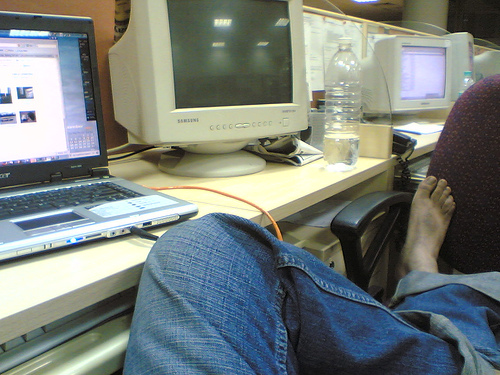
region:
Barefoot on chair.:
[397, 169, 459, 283]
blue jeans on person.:
[111, 200, 498, 372]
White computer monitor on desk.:
[107, 0, 319, 180]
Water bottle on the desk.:
[315, 30, 367, 170]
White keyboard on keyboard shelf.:
[0, 288, 135, 374]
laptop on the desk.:
[0, 9, 212, 274]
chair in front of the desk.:
[330, 71, 498, 302]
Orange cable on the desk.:
[143, 173, 286, 247]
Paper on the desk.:
[259, 135, 320, 170]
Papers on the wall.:
[300, 8, 366, 98]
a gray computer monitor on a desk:
[108, 1, 305, 173]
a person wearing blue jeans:
[123, 213, 495, 373]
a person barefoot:
[398, 175, 455, 272]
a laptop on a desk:
[0, 6, 197, 261]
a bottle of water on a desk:
[324, 33, 361, 166]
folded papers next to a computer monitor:
[250, 137, 322, 167]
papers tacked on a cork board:
[305, 9, 365, 104]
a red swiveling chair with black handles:
[331, 78, 496, 290]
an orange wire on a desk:
[148, 185, 283, 241]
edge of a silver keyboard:
[1, 290, 140, 370]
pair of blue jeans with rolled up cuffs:
[123, 194, 498, 373]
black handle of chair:
[328, 173, 427, 308]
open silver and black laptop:
[1, 6, 203, 280]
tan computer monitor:
[101, 0, 321, 186]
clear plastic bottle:
[317, 31, 367, 171]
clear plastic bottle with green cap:
[454, 66, 478, 105]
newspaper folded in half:
[246, 131, 324, 171]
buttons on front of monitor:
[201, 115, 295, 137]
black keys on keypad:
[0, 177, 147, 224]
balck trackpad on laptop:
[8, 208, 87, 235]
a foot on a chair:
[329, 126, 498, 307]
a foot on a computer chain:
[292, 104, 485, 268]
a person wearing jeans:
[158, 178, 488, 365]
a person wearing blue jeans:
[132, 184, 340, 351]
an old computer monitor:
[74, 9, 378, 239]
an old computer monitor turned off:
[112, 18, 475, 187]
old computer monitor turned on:
[335, 8, 497, 155]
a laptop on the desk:
[17, 11, 200, 261]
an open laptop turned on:
[4, 2, 253, 273]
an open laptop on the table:
[9, 2, 265, 240]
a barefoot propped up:
[362, 102, 498, 304]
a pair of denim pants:
[135, 207, 445, 372]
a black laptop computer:
[0, 8, 210, 220]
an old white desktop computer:
[100, 1, 317, 177]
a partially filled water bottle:
[320, 39, 374, 163]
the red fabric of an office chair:
[426, 78, 498, 286]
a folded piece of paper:
[249, 130, 327, 177]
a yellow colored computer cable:
[139, 174, 284, 229]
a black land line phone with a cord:
[370, 122, 432, 187]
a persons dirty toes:
[419, 172, 481, 238]